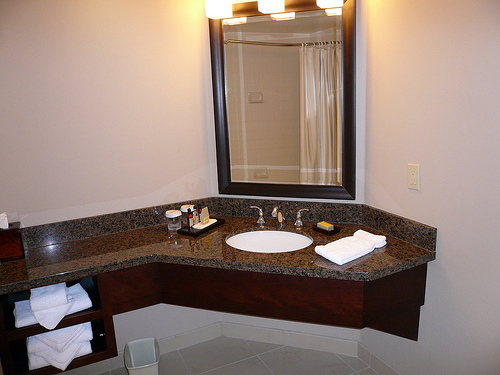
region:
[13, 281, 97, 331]
towels on the shelf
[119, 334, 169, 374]
garbage can under the sink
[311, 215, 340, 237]
bar of soap on the sink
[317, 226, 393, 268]
towel on the sink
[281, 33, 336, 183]
shower curtain in the mirror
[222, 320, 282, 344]
white baseboard below the sink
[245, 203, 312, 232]
facets and spout on the sink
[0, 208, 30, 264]
box of tissues on the sink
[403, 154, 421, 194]
outlet on the wall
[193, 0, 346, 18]
lights above the mirror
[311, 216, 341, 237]
A bar of soap in a small dish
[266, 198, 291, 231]
A silver water faucet on a sink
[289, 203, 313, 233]
A silver cold water handle on a sink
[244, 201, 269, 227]
A silver hot water handle on a sink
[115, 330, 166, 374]
A white trash can under a sink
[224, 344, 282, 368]
White tile on a bathroom floor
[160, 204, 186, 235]
A glass on a bathroom sink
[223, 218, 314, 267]
A white sink bowl in a nice counter top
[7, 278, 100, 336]
Towels folded on a shelf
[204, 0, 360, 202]
A mirror above a bathroom sink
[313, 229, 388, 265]
white towel on counter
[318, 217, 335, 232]
bar of soap on counter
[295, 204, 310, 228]
silver cold water knob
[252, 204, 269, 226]
silver hot water knob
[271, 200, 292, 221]
faucet for the sink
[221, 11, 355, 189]
mirror over the sink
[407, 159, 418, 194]
electrical outlet on wall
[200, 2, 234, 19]
light fixture on mirror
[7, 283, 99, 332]
white towels under the counter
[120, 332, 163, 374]
white trash can on ground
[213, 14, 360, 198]
a bathroom mirror over the sink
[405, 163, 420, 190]
an electrical outlet on the wall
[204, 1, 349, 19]
lights over the mirror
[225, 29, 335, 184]
reflection of a shower in the mirror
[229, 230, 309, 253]
a white sink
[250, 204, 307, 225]
silver faucet fixtures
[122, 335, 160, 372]
beige trashcan on the floor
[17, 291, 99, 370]
white towels on shelves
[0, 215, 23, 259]
a box of tissues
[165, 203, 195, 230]
drinking glasses with white paper caps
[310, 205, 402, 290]
towl on the countertop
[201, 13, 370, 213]
mirror on the wall